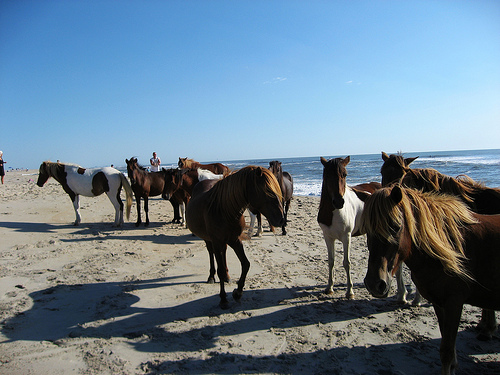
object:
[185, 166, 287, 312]
horse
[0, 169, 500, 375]
beach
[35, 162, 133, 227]
horse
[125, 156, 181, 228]
horse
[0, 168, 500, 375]
sand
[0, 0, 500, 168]
sky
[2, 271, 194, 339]
shadow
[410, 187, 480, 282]
mane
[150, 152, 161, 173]
male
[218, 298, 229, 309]
hooves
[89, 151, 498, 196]
ocean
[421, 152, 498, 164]
wave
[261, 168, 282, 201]
mane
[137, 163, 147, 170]
mane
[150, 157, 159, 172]
shirt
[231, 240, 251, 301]
leg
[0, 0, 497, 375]
picture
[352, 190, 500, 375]
horse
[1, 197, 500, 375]
foreground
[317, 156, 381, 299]
horse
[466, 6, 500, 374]
side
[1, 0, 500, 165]
background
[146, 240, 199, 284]
track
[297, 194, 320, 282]
track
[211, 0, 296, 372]
middle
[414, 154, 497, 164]
cap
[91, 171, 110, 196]
spot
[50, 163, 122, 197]
body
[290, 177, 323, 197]
foam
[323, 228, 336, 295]
legs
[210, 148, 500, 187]
water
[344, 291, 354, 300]
hooves